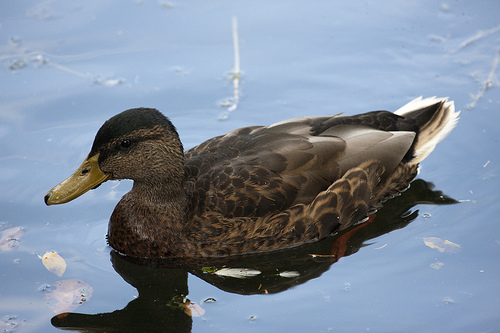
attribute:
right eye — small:
[118, 138, 130, 148]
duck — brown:
[41, 92, 460, 262]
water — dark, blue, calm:
[269, 11, 486, 103]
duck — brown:
[49, 85, 422, 302]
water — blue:
[363, 36, 406, 68]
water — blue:
[104, 21, 238, 103]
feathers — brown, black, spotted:
[101, 94, 461, 259]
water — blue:
[13, 40, 488, 319]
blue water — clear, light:
[0, 0, 499, 332]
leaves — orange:
[31, 250, 78, 283]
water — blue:
[0, 1, 499, 331]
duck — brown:
[39, 85, 466, 276]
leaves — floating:
[43, 279, 91, 315]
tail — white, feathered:
[387, 85, 466, 165]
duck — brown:
[28, 101, 492, 295]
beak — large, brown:
[41, 141, 118, 212]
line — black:
[102, 131, 163, 161]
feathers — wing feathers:
[232, 163, 312, 195]